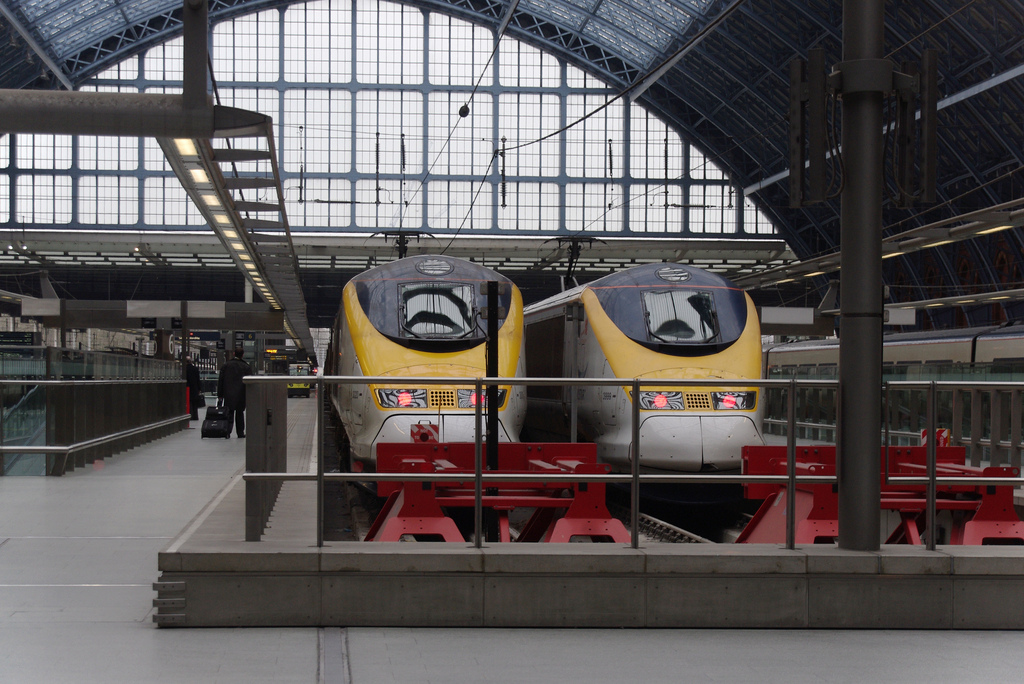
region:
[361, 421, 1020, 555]
Train stop guards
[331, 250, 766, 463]
Yellow trains inside station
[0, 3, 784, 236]
Train station windows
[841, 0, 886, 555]
Building support column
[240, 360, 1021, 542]
Steel fence separating train track area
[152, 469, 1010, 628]
Concrete fence base separating train tracks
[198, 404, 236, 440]
Suitcase being pulled by a traveller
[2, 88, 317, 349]
Train station overhead lights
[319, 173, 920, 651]
Trains on the track.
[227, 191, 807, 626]
Windows on the train.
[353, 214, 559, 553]
lights on the train.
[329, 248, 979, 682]
Red items in front of the trains.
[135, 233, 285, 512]
People walking.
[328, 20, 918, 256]
poles over the room.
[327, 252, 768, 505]
Two identical yellow and grey trains.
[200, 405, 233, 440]
Large black rolling suitcase.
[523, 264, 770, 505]
A grey and yellow train to the right of another.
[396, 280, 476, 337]
A front windshield on a train front to the left of another.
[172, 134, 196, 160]
The closest rectangle illuminated light.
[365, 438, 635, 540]
Smaller red barrier in front of a yellow and grey train.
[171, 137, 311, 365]
Long section of yellow illuminated lights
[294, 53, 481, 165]
a view of sky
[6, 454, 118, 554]
a view of floor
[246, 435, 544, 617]
a view of fence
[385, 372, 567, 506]
a view of iron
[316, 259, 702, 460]
two trains beside each other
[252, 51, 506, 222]
a view of sky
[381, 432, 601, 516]
a view of stand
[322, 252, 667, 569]
a view of train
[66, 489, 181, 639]
a view of surface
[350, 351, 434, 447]
a view of lights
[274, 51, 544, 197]
a view of fence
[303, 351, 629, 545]
a view of iron gate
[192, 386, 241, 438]
man pulling a black suitcase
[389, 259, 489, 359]
windshield on the train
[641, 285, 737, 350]
windshield on the train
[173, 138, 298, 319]
lights above the platform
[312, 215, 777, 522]
a pair of trains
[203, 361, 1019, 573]
rails near the trains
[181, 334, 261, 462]
person on the platform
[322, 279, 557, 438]
yellow front of train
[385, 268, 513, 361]
window on the train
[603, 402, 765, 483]
white bottom of train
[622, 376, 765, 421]
light on the train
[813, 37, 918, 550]
pole on the platform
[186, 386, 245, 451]
a black rolling suitcase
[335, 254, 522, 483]
the front of a train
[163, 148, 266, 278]
a light in a train station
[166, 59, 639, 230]
windows in a train station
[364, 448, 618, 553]
bumpers that are red in color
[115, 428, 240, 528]
a sidewalk that is grey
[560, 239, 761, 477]
rounded yellow train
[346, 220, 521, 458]
rounded yellow train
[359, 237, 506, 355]
black train roof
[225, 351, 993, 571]
silver metal fence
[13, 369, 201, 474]
silver metal fence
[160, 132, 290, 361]
row of overhead lights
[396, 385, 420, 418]
red train headlight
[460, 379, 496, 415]
red train headlight